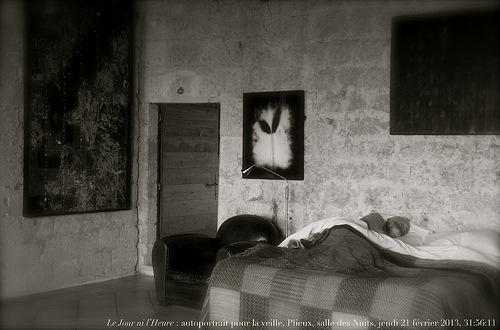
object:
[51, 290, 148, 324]
tiles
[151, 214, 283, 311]
chair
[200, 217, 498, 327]
bedspread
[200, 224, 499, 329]
blanket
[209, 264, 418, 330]
checkered pattern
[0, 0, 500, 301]
wall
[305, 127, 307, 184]
ground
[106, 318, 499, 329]
description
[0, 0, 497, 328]
photo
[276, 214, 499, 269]
white sheet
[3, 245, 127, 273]
stone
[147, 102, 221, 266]
door way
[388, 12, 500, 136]
painting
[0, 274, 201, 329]
floor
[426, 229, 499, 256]
pillow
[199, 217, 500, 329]
sheets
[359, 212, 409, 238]
man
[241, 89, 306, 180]
picture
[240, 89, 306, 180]
frame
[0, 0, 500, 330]
bedroom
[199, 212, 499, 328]
bed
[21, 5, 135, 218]
painting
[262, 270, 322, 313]
print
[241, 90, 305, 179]
painting